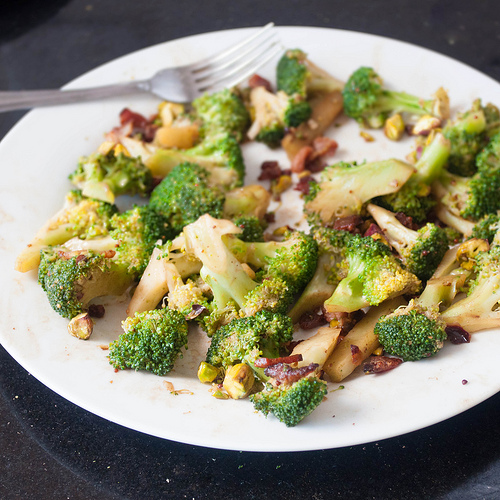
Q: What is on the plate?
A: Salad.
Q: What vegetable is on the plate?
A: Broccoli.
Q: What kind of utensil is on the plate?
A: A fork.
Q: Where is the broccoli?
A: On a plate.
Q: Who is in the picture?
A: Nobody.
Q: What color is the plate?
A: White.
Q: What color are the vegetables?
A: Green.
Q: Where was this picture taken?
A: On the table.